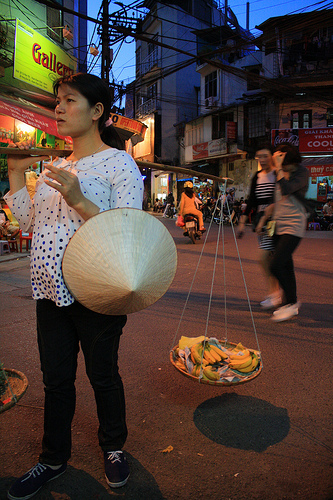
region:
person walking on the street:
[253, 137, 318, 325]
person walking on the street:
[244, 142, 280, 315]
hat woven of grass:
[59, 206, 184, 325]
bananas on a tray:
[165, 330, 265, 390]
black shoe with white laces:
[97, 437, 134, 496]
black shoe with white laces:
[6, 446, 75, 498]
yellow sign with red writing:
[5, 13, 81, 113]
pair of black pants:
[30, 279, 136, 470]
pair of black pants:
[263, 225, 307, 309]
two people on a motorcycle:
[173, 177, 210, 248]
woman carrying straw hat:
[49, 195, 185, 340]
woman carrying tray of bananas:
[167, 314, 303, 407]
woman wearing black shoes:
[33, 458, 174, 497]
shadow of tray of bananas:
[194, 391, 285, 465]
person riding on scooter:
[177, 177, 212, 245]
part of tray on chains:
[0, 341, 46, 428]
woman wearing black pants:
[47, 303, 166, 437]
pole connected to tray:
[162, 151, 246, 202]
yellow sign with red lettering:
[11, 22, 98, 104]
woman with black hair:
[44, 71, 109, 130]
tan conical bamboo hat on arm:
[61, 207, 179, 315]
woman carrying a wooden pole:
[0, 145, 234, 186]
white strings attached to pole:
[170, 178, 265, 383]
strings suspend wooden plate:
[168, 195, 265, 385]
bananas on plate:
[229, 349, 258, 374]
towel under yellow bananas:
[180, 335, 258, 381]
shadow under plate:
[191, 391, 293, 455]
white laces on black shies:
[106, 449, 126, 464]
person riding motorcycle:
[174, 180, 209, 244]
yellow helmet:
[182, 181, 192, 189]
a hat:
[33, 173, 145, 290]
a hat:
[50, 189, 177, 324]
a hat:
[75, 230, 168, 338]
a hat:
[56, 228, 201, 388]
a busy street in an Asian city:
[21, 66, 312, 267]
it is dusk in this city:
[78, 4, 297, 124]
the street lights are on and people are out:
[31, 73, 321, 286]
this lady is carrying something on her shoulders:
[20, 51, 274, 286]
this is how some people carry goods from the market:
[65, 93, 265, 338]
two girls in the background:
[241, 129, 325, 332]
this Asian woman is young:
[22, 64, 148, 253]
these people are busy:
[158, 151, 257, 248]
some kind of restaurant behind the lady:
[3, 39, 110, 263]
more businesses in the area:
[173, 106, 329, 252]